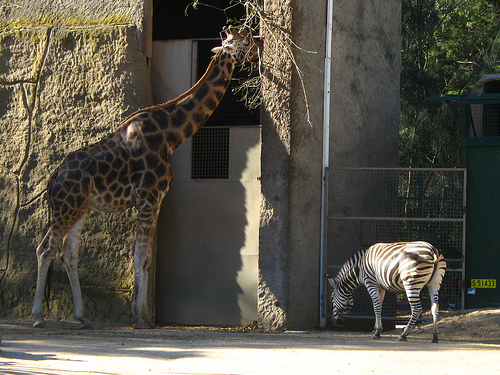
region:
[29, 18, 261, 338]
giraffe eating from a building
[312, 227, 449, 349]
zebra standing on the concrete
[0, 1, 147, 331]
stone wall in the animal exhibit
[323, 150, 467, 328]
chain link fence in the animal habitat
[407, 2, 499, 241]
large tree next to the building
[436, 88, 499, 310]
green partition in the exhibit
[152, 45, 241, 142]
neck of the giraffe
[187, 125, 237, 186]
wire window on the wall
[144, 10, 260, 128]
opening for the giraffe to eat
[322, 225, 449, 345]
zebra bending down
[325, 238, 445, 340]
a black and white stripped zebra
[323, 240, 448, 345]
a zebra looking for food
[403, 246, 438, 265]
a zebras tail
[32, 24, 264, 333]
a tall spotted giraffe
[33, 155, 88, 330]
a back pair of giraffe's legs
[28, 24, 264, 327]
a tall brown giraffe eating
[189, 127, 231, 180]
a grate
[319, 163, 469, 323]
a metal chained link fence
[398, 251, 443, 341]
the back legs of a zebra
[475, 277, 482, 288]
the number 5 in black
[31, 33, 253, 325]
the giraffe is tall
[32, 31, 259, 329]
the giraffe has spots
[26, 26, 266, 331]
the giraffe is eating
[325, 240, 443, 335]
the zebra is small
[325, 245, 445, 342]
the zebra is looking down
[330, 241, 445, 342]
the zebra has stripes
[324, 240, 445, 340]
the zebra is white and black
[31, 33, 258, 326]
the giraffe is brown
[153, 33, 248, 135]
the giraffe has a long neck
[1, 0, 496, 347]
the scene takes place outdoors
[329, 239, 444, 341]
A zebra in the enclosure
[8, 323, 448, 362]
A shadow on the ground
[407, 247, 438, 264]
The tail of the zebra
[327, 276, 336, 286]
The left ear of the zebra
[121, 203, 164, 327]
The front legs of the giraffe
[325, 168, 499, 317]
A fence in the enclosure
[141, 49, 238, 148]
The giraffe has a long neck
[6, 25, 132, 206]
A crack in the wall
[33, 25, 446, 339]
A zebra and a giraffe in an enclosure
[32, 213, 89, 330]
The back legs of the giraffe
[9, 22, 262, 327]
giraffe beside the building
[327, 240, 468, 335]
zebra beside the fence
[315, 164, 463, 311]
the fence is chain link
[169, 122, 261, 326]
the door on the building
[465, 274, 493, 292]
the number plate beside the fence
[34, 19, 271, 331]
the giraffe eating the branch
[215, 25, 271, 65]
head of the giraffe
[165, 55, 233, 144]
the neck of the giraffe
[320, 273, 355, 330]
head of the zebra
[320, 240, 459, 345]
the zebra is striped